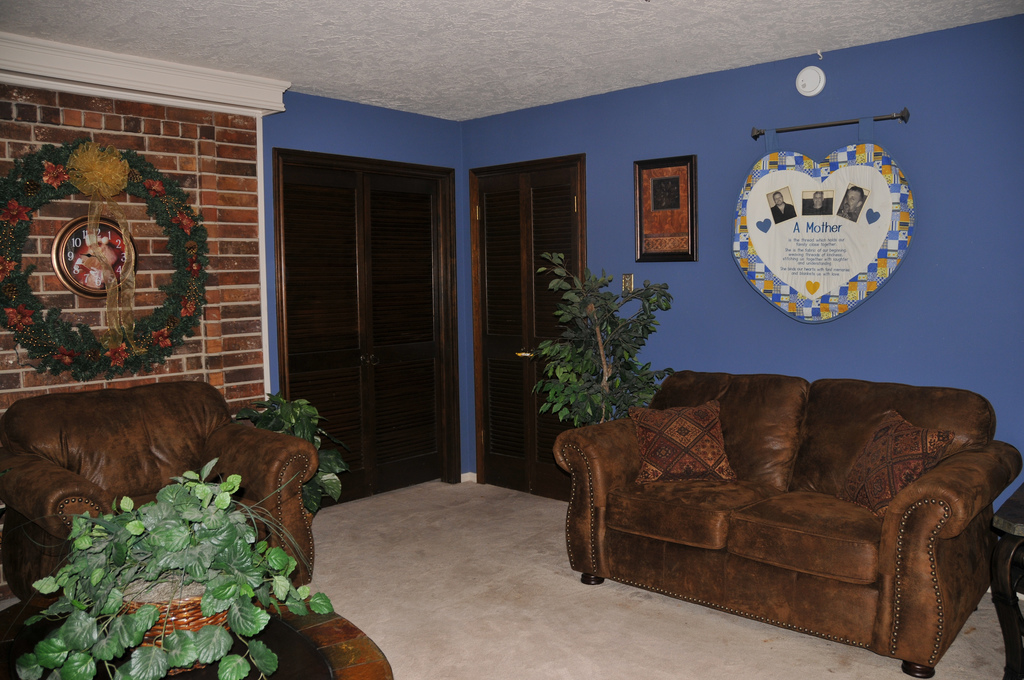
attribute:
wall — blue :
[455, 14, 1017, 485]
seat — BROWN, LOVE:
[600, 383, 942, 647]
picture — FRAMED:
[615, 145, 685, 266]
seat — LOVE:
[570, 351, 972, 647]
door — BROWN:
[481, 217, 538, 378]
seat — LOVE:
[576, 318, 970, 643]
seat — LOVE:
[565, 363, 957, 632]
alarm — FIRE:
[772, 53, 842, 97]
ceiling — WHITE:
[388, 29, 488, 56]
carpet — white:
[481, 541, 594, 624]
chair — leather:
[13, 404, 325, 586]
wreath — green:
[24, 130, 241, 420]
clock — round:
[52, 214, 143, 308]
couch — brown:
[576, 351, 1017, 669]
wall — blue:
[616, 85, 1018, 453]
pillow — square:
[609, 387, 750, 502]